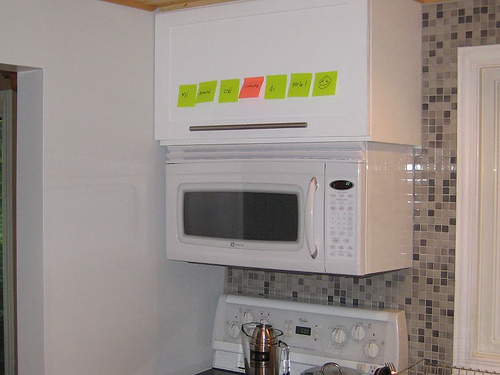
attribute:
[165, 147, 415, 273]
microwave — white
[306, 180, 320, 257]
handle — white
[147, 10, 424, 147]
cabinet — wooden, white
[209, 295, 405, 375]
stove — white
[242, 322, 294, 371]
measuring cup — glass, clear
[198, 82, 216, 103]
sticky note — green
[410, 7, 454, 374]
tile — gray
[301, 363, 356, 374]
lid — gray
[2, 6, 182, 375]
wall — white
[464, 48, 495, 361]
door frame — white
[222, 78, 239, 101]
post it note — green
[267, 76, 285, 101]
post it note — green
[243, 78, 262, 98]
sticky note — pink, red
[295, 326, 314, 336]
screen — black